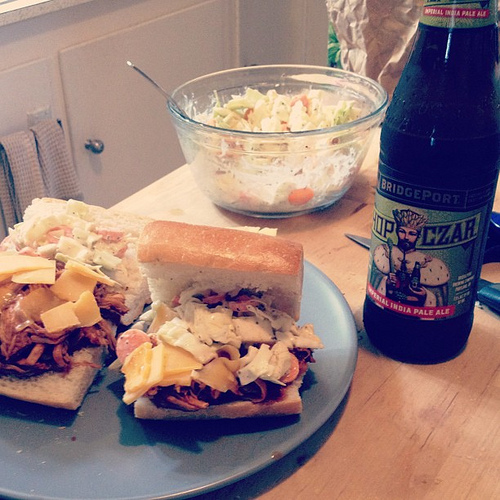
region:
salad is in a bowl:
[157, 48, 389, 192]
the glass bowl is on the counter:
[174, 39, 484, 252]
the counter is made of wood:
[363, 405, 489, 460]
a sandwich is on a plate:
[125, 200, 358, 496]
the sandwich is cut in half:
[132, 230, 317, 420]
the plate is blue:
[14, 160, 353, 485]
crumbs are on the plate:
[15, 413, 145, 493]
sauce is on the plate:
[245, 451, 335, 476]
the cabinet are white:
[52, 48, 327, 194]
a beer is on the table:
[355, 123, 462, 328]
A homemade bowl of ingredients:
[136, 48, 395, 223]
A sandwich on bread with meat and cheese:
[0, 194, 317, 431]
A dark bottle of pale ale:
[361, 0, 498, 365]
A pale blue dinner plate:
[6, 272, 360, 496]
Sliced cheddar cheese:
[119, 340, 237, 401]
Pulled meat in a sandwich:
[2, 321, 114, 383]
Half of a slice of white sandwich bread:
[135, 216, 310, 301]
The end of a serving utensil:
[119, 51, 204, 126]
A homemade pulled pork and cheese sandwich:
[1, 184, 336, 443]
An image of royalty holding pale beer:
[369, 204, 453, 317]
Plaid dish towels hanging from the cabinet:
[3, 128, 81, 225]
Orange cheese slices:
[120, 345, 192, 395]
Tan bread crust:
[143, 223, 305, 315]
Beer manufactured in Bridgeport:
[377, 173, 473, 213]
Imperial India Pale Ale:
[366, 283, 454, 319]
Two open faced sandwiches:
[0, 191, 318, 419]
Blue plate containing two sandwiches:
[1, 210, 361, 497]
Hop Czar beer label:
[361, 200, 486, 322]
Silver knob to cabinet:
[84, 136, 104, 153]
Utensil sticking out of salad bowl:
[122, 50, 382, 220]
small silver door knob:
[84, 137, 111, 156]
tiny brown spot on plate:
[258, 447, 294, 463]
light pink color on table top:
[387, 378, 459, 469]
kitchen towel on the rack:
[4, 127, 94, 189]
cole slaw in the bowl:
[213, 98, 292, 123]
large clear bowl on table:
[159, 57, 391, 202]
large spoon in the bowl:
[117, 54, 223, 127]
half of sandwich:
[117, 216, 327, 416]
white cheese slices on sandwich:
[122, 335, 208, 372]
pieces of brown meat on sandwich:
[137, 382, 217, 411]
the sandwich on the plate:
[2, 185, 372, 495]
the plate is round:
[6, 228, 345, 498]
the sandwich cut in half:
[10, 198, 330, 445]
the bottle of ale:
[351, 3, 494, 385]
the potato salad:
[122, 43, 375, 228]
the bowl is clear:
[148, 54, 395, 231]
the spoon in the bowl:
[87, 43, 233, 134]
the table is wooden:
[331, 398, 493, 496]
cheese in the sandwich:
[97, 341, 191, 384]